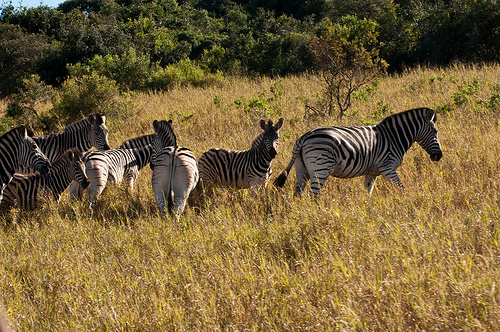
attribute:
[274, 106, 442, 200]
zebra — looking, facing, white, walking, adult, small, black, baby, bunch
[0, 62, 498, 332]
grass — brown, brownish, growing, tall, yellow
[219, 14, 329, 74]
bushes — greenish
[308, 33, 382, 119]
tree — green, growing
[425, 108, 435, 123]
ear — pointed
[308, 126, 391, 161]
hair — short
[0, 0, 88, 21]
sky — blueish, blue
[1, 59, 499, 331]
field — grassy